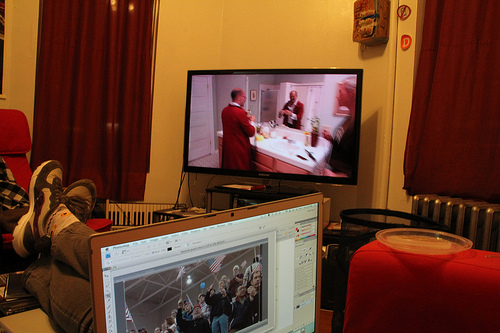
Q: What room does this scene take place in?
A: Living room.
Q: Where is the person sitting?
A: On the couch.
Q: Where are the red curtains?
A: On the windows.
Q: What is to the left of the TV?
A: Keyboard.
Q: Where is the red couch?
A: Under the sitting man.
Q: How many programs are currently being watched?
A: 2.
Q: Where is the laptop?
A: On the man's lap.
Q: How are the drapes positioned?
A: Closed.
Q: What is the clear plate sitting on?
A: The arm of a red couch.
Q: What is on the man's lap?
A: An open laptop.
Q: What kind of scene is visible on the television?
A: A bathroom scene.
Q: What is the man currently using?
A: A laptop.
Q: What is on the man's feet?
A: Tennis shoes.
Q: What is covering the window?
A: Red curtains.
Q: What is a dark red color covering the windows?
A: The curtains.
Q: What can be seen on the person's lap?
A: The monitor of a laptop.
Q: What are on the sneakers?
A: Gray laces.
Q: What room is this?
A: Living room.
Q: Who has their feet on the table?
A: Person.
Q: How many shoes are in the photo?
A: Two.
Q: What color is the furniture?
A: Red.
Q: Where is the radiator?
A: By the window.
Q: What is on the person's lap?
A: Computer.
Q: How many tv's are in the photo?
A: One.